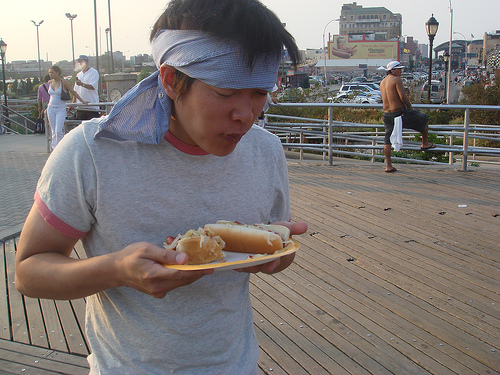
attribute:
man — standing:
[381, 57, 433, 174]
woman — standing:
[45, 70, 66, 143]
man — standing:
[71, 55, 95, 110]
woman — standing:
[40, 78, 51, 150]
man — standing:
[16, 2, 304, 371]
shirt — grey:
[84, 130, 198, 197]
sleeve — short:
[34, 145, 96, 226]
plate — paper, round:
[163, 235, 296, 265]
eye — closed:
[213, 89, 239, 102]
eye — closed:
[257, 90, 270, 100]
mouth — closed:
[218, 129, 247, 144]